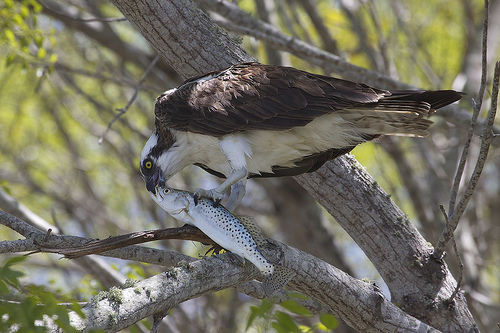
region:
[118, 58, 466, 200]
black and white bird in a tree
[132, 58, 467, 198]
black and white bird with fish in its mouth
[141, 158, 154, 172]
black and white birds yellow eye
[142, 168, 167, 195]
black and white birds beak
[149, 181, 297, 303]
fish that the bird is eating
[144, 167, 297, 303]
fish that the bird has caught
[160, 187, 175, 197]
fish's yellow eye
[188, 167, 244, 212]
birds left leg and claw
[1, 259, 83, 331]
leaves in the tree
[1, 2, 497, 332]
tree that the bird is perched in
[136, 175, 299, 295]
A dark spotted fish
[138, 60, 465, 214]
A predatory bird eating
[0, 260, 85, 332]
Green foliage of a tree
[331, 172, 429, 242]
Grayish veined tree bark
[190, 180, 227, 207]
Talon of a predatory bird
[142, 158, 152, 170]
Golden eye of a warlike bird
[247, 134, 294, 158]
White downy under feathers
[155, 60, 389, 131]
Wings with black sheen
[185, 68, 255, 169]
A drumstick with skin and feathers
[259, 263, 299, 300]
The tail of a fish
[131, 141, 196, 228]
bird head and a fish head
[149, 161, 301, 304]
fish in a bird's talon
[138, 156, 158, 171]
yellow eye on a bird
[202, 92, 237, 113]
brown feathers on a wing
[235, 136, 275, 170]
white feathers on a bird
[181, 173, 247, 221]
white talon's of a bird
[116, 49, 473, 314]
a bird eating a fish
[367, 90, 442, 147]
brown and white tail feathers on a bird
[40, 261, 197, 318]
moss growing on a branch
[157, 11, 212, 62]
bark on a tree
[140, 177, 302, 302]
Small black and white fish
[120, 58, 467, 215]
Black and white bird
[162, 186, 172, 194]
Small black and yellow eye of fish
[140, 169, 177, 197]
Birds black beak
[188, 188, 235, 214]
Two black bird claws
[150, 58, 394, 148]
Bird has black wing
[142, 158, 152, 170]
Small black and yellow eye on bird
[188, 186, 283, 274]
Black spots on white fish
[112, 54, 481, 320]
Bird eating a fish in the tree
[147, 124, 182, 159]
Black stripe on birds head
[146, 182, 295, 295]
a white speckled fish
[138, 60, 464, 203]
a bird with a fish in its mouth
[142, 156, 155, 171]
the yellow eye of a bird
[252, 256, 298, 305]
the tail of a fish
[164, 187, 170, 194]
the eye of a fish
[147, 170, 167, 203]
the mouth of a fish in a bird's beak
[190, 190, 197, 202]
the black claw of a bird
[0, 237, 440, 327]
the branch of a tree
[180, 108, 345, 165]
the white underbelly of a bird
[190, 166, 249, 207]
the leg of a bird